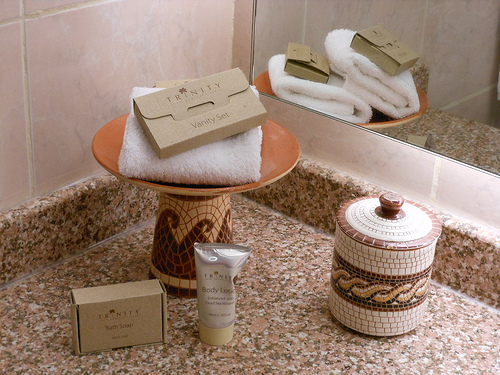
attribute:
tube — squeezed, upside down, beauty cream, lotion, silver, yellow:
[192, 232, 251, 346]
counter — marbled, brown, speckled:
[1, 157, 498, 373]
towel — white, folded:
[120, 82, 265, 185]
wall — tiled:
[2, 1, 252, 213]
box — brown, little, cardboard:
[66, 278, 171, 356]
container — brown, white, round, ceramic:
[327, 190, 443, 339]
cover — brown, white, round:
[335, 189, 443, 251]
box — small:
[128, 65, 268, 160]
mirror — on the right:
[252, 4, 500, 178]